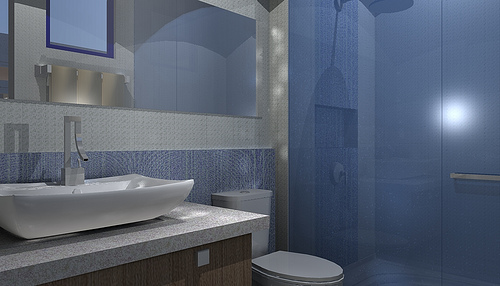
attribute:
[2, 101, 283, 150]
stripe — white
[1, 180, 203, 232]
sink — white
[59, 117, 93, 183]
faucet — metal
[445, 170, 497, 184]
bar — silver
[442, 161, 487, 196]
bar — metal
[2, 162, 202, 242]
sink bowl — white, raised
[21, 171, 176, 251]
sink — white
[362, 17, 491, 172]
bathroom walls — blue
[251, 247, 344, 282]
lid — down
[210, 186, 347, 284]
toilet — white